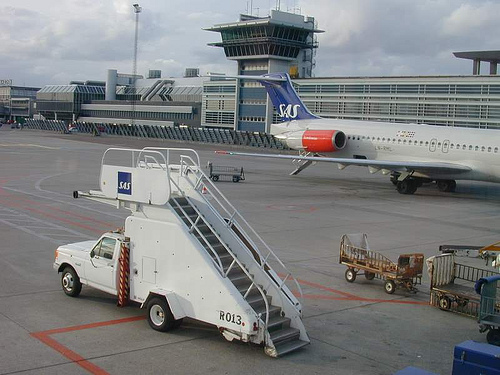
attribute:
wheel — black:
[138, 293, 177, 331]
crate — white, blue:
[258, 72, 318, 133]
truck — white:
[57, 141, 328, 368]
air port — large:
[0, 66, 497, 373]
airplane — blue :
[215, 71, 498, 190]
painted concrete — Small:
[27, 312, 147, 373]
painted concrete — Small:
[297, 278, 431, 305]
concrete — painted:
[16, 319, 156, 371]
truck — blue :
[53, 144, 310, 355]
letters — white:
[269, 81, 306, 128]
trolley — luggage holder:
[330, 226, 499, 337]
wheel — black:
[368, 171, 431, 216]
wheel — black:
[371, 266, 411, 313]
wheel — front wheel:
[62, 267, 83, 297]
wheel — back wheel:
[148, 297, 173, 329]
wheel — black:
[138, 281, 163, 332]